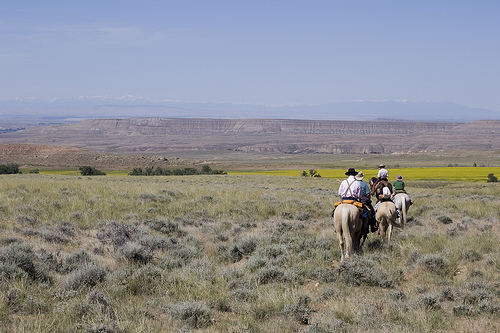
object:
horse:
[333, 203, 370, 261]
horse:
[390, 188, 411, 226]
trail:
[2, 173, 497, 331]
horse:
[369, 177, 393, 199]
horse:
[374, 201, 397, 241]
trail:
[274, 140, 477, 175]